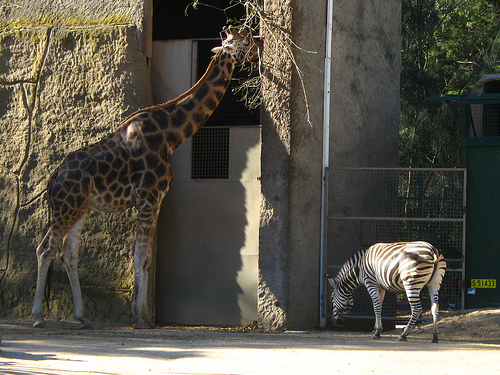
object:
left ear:
[324, 270, 334, 285]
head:
[322, 279, 354, 325]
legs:
[141, 201, 158, 331]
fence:
[321, 165, 466, 335]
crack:
[0, 23, 57, 280]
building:
[0, 0, 401, 336]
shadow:
[65, 330, 122, 350]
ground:
[170, 343, 497, 370]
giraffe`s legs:
[30, 187, 91, 329]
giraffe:
[21, 24, 264, 332]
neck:
[153, 55, 233, 160]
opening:
[186, 33, 272, 134]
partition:
[456, 97, 498, 298]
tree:
[396, 4, 449, 224]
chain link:
[317, 154, 477, 326]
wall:
[26, 18, 58, 107]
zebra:
[317, 238, 451, 343]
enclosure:
[4, 5, 493, 335]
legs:
[58, 209, 91, 334]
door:
[148, 31, 262, 334]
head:
[214, 20, 266, 66]